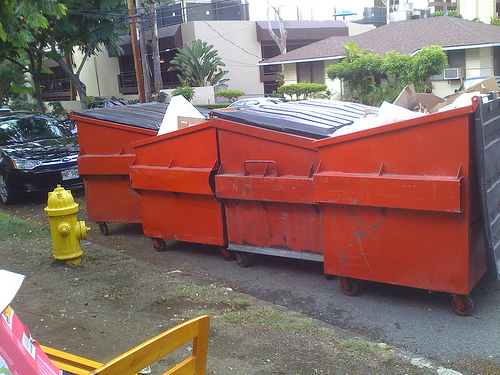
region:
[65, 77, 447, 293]
red and black bins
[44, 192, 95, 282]
yellow hydrant on grass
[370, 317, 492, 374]
road is dark grey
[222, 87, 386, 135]
black cover on bin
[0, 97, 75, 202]
black car near bins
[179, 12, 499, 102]
white buildings behind bins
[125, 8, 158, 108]
brown pole behind bins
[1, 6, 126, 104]
green tree behind black car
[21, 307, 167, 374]
brown chair near hydrant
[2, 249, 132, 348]
brown ground around hydrant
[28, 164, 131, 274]
This is an oil hydrant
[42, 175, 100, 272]
This is an oil hydrant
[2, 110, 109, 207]
This is a car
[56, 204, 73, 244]
fire hydrant is yellow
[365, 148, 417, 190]
the trash can is red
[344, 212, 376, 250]
the paint is chipping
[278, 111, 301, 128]
the lid is black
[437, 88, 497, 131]
the lid is open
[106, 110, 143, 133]
the lid is closed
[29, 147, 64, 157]
the car is black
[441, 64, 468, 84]
the ac is in the window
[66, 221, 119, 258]
the hydrant is by the curb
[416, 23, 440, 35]
the roof is brown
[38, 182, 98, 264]
A yellow fire hydrant.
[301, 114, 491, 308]
A red trash dumpster.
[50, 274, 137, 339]
Dirt on the ground.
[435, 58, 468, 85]
An air conditioner in the window.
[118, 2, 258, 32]
The telephone lines.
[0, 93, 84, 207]
A black car on the street.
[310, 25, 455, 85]
A tree in front of the house.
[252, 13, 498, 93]
A house in the background.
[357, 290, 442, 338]
The paved street.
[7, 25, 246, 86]
An apartment building.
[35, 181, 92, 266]
Yellow fire hydrant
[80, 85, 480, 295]
Four large garbage dumpsters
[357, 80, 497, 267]
Lid open on dumpster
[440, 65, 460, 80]
Window air conditioner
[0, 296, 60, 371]
Pink box on a yellow cart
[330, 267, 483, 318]
Orange wheels on an orange dumpster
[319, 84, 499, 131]
Trash sticking out of the dumpster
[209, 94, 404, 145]
Closed black lid on dumpster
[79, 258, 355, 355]
Trash on the ground around dumpsters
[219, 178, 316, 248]
Rust and dirt on the side of the dumpster